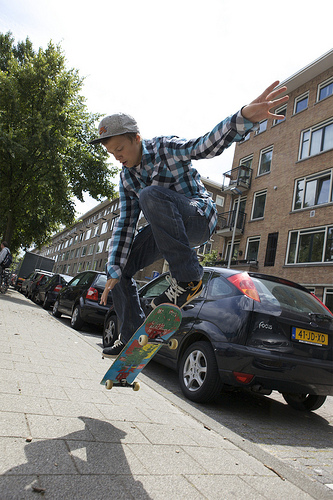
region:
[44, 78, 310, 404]
young an skating on a skateboard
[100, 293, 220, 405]
colorful skateboard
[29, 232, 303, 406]
row of cars parked on a street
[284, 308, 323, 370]
yellow license plate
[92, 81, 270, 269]
plaid shirt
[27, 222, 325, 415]
bunch of cars parked along the sidewalk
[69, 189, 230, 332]
denim jeans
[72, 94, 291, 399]
a skateboarder jumping on a skateboard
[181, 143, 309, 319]
brick apartment building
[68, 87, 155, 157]
gray baseball cap with a red logo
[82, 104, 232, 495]
A young boy on skateboard.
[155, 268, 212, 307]
Black tennis shoe with yellow stripe.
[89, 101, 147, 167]
Grey hat on boy's head.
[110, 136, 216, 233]
Black, blue and white striped shirt.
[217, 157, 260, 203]
A balcony on a building.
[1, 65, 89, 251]
A green tree on right side.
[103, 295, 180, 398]
A multi-colored skateboard.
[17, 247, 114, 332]
Cars parked on the street.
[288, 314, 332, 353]
Yellow license tag on car.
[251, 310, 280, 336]
The word focus on back of car.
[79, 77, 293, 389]
Person riding a skateboard.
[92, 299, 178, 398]
Skateboard in the air.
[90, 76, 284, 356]
Person wearing a hat.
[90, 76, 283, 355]
Person wearing a pair of jeans.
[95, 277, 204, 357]
Pair of black shoes.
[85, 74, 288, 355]
Person wearing a blue shirt.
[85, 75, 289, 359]
Person wearing black shoes.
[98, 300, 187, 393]
Skateboard with white wheels.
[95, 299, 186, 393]
Blue and green skateboard.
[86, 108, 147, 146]
Gray and orange hat.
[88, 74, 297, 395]
balancing during a trick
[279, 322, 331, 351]
a yellow auto tag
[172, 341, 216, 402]
an aluminum wheel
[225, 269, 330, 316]
highly visible brake lights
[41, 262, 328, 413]
three black cars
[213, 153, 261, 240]
balconies on a building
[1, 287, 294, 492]
a stone side walk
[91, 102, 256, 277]
a blue and white patterned shirt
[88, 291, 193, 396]
a multi-colored skate board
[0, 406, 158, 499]
shadow on a sidewalk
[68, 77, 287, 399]
The boy is on a skateboard.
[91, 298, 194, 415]
The skateboard is in the air.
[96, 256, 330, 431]
A black car is parked behind the boy.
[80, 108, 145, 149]
The boy wears a cap.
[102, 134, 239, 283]
The boy wears a blue checkered shirt.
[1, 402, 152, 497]
The boy's shadow is on the ground.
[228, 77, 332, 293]
There is a building in the background.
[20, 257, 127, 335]
Cars are parked ahead on the street.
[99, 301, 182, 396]
The skateboard is green, blue, yellow, and red.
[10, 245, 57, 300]
There is a truck parked on the side of the street.